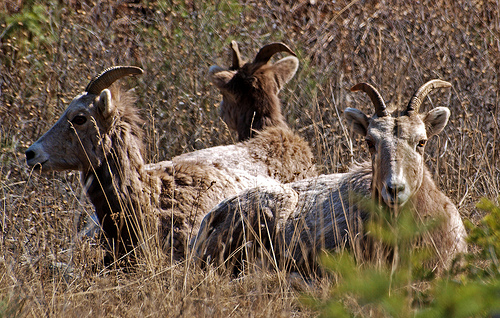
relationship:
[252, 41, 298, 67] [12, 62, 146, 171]
horn over head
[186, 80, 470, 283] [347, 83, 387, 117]
ram has horn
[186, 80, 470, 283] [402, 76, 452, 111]
ram has horn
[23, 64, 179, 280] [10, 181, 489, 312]
animals lying on ground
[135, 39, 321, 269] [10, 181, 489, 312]
animal lying on ground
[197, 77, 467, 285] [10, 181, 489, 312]
animal lying on ground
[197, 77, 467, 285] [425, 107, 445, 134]
animal has ear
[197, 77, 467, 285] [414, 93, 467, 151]
animal has left ear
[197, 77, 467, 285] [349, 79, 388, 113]
animal has horn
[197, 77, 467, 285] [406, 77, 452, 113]
animal has horn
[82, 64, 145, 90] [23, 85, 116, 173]
horn on head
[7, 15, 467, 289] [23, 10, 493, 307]
grass in field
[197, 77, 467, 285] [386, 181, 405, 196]
animal has nose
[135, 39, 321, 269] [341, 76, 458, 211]
animal has head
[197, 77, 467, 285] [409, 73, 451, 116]
animal has horn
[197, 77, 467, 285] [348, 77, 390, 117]
animal has horn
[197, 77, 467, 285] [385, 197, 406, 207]
animal has mouth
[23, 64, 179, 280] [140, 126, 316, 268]
animals has body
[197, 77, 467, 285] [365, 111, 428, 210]
animal has face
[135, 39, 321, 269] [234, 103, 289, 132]
animal has neck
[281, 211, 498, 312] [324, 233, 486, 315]
tree has branch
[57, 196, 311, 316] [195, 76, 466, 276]
weeds under animal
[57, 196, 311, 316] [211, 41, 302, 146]
weeds under animal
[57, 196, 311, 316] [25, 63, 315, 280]
weeds under animal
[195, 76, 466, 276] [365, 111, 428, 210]
animal has face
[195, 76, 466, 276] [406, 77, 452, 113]
animal has horn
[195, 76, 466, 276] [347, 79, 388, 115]
animal has horn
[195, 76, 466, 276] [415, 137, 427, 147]
animal has eye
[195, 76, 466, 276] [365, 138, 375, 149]
animal has eye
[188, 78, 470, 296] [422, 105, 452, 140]
animal has ear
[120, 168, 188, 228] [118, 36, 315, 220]
fur of animal